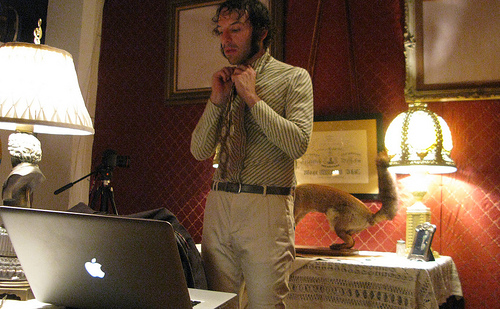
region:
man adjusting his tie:
[188, 1, 315, 307]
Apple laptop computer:
[1, 201, 200, 307]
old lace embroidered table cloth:
[282, 246, 464, 306]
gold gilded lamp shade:
[379, 101, 459, 173]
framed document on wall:
[286, 108, 386, 204]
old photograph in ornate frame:
[406, 219, 437, 262]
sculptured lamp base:
[0, 131, 50, 210]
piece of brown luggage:
[67, 199, 206, 288]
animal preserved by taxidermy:
[291, 148, 399, 256]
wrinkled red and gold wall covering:
[89, 0, 497, 307]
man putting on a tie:
[191, 5, 301, 301]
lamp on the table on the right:
[383, 100, 449, 260]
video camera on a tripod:
[52, 147, 127, 212]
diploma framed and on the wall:
[290, 115, 375, 195]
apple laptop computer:
[0, 206, 235, 303]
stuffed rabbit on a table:
[290, 182, 370, 247]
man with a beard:
[190, 2, 310, 303]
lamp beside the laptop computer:
[5, 42, 87, 297]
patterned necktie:
[227, 75, 247, 178]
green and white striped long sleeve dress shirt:
[192, 51, 309, 188]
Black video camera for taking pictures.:
[53, 144, 138, 212]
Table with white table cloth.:
[242, 227, 472, 304]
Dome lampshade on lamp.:
[382, 91, 454, 254]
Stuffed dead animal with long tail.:
[291, 152, 406, 249]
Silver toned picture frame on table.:
[407, 219, 439, 262]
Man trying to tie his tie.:
[196, 5, 318, 299]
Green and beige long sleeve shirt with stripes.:
[189, 8, 311, 303]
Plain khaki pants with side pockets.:
[198, 7, 312, 306]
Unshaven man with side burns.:
[191, 5, 311, 306]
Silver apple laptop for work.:
[5, 198, 236, 305]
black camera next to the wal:
[51, 147, 136, 214]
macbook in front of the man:
[0, 203, 246, 305]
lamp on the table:
[380, 97, 455, 257]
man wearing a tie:
[185, 0, 310, 305]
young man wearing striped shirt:
[185, 0, 311, 305]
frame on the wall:
[400, 0, 497, 105]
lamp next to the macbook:
[0, 16, 95, 306]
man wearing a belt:
[190, 1, 317, 308]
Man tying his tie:
[186, 0, 312, 305]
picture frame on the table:
[407, 224, 437, 261]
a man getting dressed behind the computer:
[188, 0, 315, 307]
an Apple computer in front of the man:
[0, 203, 233, 306]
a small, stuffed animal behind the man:
[297, 145, 398, 253]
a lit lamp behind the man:
[384, 98, 454, 253]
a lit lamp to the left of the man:
[0, 15, 93, 198]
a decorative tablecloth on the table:
[281, 242, 464, 307]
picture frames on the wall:
[169, 0, 499, 105]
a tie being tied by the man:
[226, 70, 248, 180]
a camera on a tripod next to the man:
[53, 150, 131, 215]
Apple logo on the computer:
[82, 256, 104, 278]